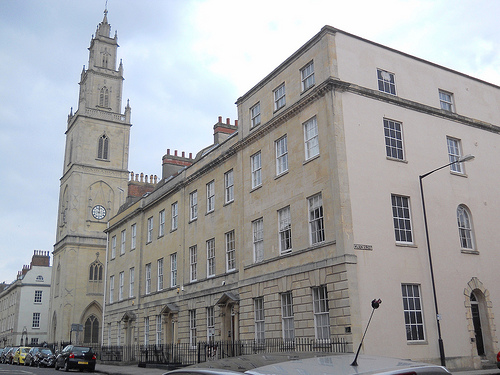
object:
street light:
[416, 152, 478, 374]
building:
[92, 22, 500, 375]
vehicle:
[51, 343, 99, 374]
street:
[1, 359, 172, 375]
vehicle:
[23, 345, 58, 367]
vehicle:
[11, 345, 30, 365]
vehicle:
[2, 344, 19, 365]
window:
[387, 191, 418, 251]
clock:
[90, 204, 107, 221]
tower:
[47, 0, 138, 365]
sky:
[0, 0, 500, 287]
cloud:
[173, 0, 431, 102]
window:
[381, 114, 409, 163]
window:
[375, 65, 400, 97]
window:
[454, 201, 481, 255]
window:
[445, 133, 468, 179]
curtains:
[306, 118, 320, 158]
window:
[299, 111, 322, 167]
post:
[417, 172, 447, 371]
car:
[150, 295, 454, 375]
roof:
[161, 349, 449, 375]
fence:
[0, 336, 347, 368]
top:
[83, 335, 349, 349]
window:
[251, 213, 266, 265]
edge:
[328, 74, 500, 135]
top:
[229, 15, 500, 150]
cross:
[102, 0, 109, 15]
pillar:
[232, 303, 240, 357]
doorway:
[223, 300, 239, 357]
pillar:
[220, 305, 226, 358]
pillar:
[171, 315, 178, 365]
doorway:
[162, 313, 177, 363]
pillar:
[162, 316, 169, 365]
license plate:
[77, 360, 91, 365]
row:
[0, 341, 97, 372]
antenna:
[349, 296, 384, 367]